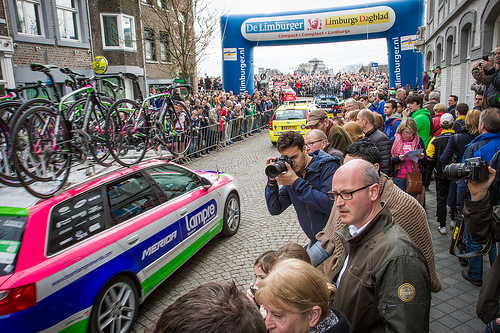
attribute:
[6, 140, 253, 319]
car — white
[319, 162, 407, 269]
man — light skinned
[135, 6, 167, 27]
wall — brown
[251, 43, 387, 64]
clouds — white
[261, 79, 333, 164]
car — blue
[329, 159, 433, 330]
man — light skinned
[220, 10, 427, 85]
line — finishing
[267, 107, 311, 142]
car — yellow